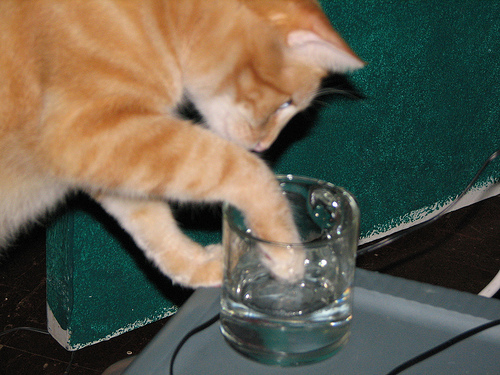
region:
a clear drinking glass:
[204, 184, 375, 351]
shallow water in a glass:
[229, 267, 338, 331]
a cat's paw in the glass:
[239, 184, 334, 304]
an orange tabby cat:
[9, 0, 366, 221]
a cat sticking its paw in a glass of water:
[9, 2, 420, 367]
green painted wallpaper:
[351, 4, 491, 126]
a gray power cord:
[429, 159, 492, 220]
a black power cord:
[411, 316, 447, 372]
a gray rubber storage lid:
[371, 267, 438, 369]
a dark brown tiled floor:
[432, 231, 498, 281]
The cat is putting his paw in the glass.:
[0, 1, 471, 367]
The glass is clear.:
[213, 178, 364, 368]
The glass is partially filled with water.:
[215, 270, 365, 366]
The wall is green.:
[375, 15, 475, 141]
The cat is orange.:
[6, 0, 343, 365]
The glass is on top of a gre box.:
[146, 177, 486, 372]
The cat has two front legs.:
[106, 120, 313, 295]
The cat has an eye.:
[261, 70, 296, 112]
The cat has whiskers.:
[190, 83, 265, 163]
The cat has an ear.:
[284, 6, 381, 83]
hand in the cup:
[225, 172, 304, 277]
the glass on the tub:
[212, 173, 363, 365]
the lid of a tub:
[368, 277, 498, 340]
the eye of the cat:
[271, 89, 295, 111]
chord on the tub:
[385, 304, 497, 373]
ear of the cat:
[289, 15, 368, 75]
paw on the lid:
[172, 237, 220, 296]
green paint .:
[402, 50, 442, 156]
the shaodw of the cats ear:
[317, 80, 367, 169]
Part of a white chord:
[481, 267, 498, 302]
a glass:
[211, 140, 359, 372]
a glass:
[236, 136, 305, 373]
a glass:
[254, 243, 314, 354]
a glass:
[219, 149, 295, 286]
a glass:
[189, 211, 243, 327]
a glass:
[320, 176, 355, 355]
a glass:
[296, 144, 348, 370]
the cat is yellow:
[0, 0, 377, 301]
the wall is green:
[44, 2, 499, 356]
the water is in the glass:
[211, 165, 359, 373]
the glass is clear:
[212, 164, 360, 374]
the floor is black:
[0, 196, 499, 371]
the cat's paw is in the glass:
[227, 142, 320, 287]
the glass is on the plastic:
[109, 242, 496, 373]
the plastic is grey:
[115, 248, 499, 373]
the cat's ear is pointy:
[286, 7, 369, 85]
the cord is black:
[158, 302, 498, 373]